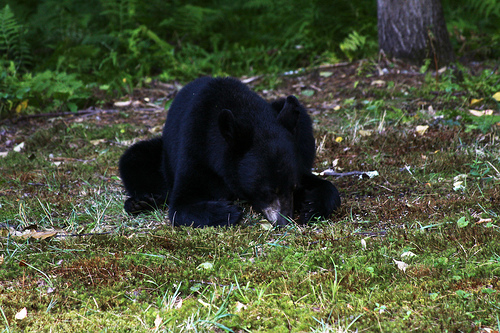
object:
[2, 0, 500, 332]
grass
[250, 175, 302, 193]
eyes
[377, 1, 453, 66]
tree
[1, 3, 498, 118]
ferns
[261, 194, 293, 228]
muzzle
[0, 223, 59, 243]
sanwiches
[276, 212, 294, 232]
nose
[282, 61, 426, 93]
dirt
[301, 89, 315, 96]
leaves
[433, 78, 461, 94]
leaves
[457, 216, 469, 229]
leaves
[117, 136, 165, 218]
leg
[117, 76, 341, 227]
bear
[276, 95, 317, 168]
black leg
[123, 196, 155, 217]
paw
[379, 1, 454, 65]
tree trunk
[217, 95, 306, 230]
head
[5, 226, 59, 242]
leaf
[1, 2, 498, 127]
foliage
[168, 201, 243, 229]
bear's paw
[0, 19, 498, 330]
grass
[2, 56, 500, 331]
ground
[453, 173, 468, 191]
leaf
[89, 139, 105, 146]
leaf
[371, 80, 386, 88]
leaf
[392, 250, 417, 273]
leaf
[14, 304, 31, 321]
leaf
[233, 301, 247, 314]
leaf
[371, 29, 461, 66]
bottom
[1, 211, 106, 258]
branch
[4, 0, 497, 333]
woods